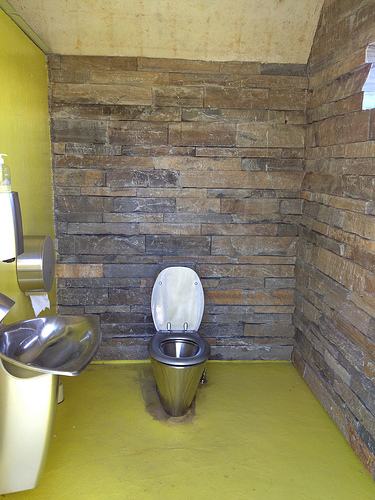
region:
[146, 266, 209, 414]
A brushed steel toilet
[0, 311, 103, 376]
Steel basin of a sink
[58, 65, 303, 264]
Stone bricks on a wall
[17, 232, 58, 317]
Steel holder for toilet paper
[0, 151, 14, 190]
Bottle of hand sanitizing solution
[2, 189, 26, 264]
Brushed steel soap dispenser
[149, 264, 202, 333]
Underside of a toilet lid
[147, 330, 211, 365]
Toilet seat lowered over the rim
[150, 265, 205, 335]
Toilet seat lid standing upright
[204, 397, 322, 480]
Plain, yellow floor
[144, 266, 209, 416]
A metal toilet in a room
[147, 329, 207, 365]
Toilet seat that is metal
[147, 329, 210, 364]
Metal toilet seat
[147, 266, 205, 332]
A toilet seat lid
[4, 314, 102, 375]
Bathroom sink that is metal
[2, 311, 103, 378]
A metal bathroom sink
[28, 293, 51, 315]
paper towel coming out a dispenser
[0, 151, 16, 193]
A soap bottle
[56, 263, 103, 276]
A single brick on a wall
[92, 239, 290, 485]
view is in a bathroom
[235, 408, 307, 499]
floor is bright yello in color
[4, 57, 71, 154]
wall is yellow in color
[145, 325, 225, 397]
the toilet is open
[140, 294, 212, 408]
the toilet is silvery in color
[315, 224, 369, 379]
the wall is brown bricked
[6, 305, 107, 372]
sink is silvery in color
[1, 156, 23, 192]
a bottle of handwash on the wall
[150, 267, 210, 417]
A silver metal bathroom toilet.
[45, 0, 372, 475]
Two stone brick walls.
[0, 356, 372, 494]
A green bathroom floor.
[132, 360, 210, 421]
Stains on the floor around the toilet.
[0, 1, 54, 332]
A green painted wall.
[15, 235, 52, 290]
A round silver toilet paper dispenser.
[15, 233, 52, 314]
White paper sticking out of the dispenser.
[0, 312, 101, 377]
A silver metal sink.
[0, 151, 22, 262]
A bottle of soap sitting on top of a soap dispenser.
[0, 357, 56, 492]
A white garbage pail below the sink.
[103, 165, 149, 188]
A brick in a wall.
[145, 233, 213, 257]
A brick in a wall.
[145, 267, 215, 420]
metal toilet in the bathroom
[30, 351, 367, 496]
green floor in the bathroom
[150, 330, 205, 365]
metal seat on the toilet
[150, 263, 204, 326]
lifted lid on the toilet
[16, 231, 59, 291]
metal toilet dispenser on the wall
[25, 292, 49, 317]
toilet paper from the dispenser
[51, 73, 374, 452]
stone walls in the bathroom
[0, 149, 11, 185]
clear plastic bottle with pump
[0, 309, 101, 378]
silver sink in the bathroom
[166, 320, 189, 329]
hinges on the toilet seat